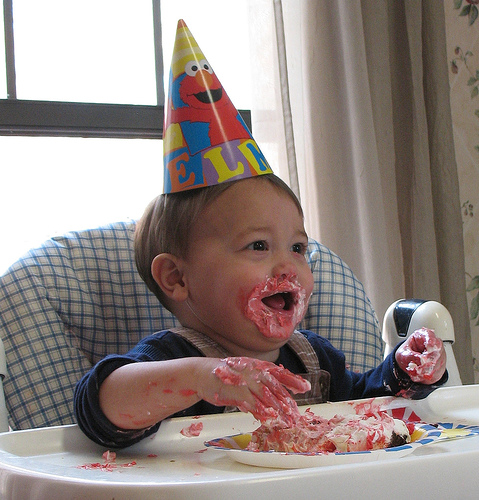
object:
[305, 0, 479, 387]
curtain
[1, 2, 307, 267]
window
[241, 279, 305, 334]
cream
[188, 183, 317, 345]
face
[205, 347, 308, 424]
hand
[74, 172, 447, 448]
child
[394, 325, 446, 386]
hand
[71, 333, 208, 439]
sleeve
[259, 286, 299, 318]
mouth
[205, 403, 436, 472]
plate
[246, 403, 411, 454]
cake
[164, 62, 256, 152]
elmo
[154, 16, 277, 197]
party hat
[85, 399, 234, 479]
frosting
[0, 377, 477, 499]
table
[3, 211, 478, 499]
high chair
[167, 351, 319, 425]
frosting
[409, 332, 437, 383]
frosting